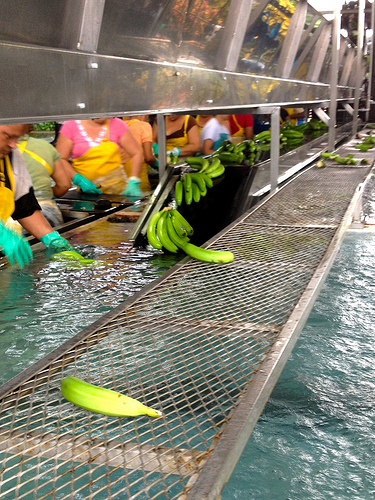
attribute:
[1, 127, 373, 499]
shelf — metal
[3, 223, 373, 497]
water — large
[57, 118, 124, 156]
shirt — white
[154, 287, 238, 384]
grate — large, silver, iron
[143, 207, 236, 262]
banana — green, yellow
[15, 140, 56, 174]
strap — yellow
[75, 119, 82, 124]
dot — white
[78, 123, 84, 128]
dot — white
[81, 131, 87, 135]
dot — white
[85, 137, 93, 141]
dot — white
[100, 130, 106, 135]
dot — white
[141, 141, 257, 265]
bananas — green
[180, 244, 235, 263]
banana — single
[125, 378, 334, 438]
object — black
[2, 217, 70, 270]
gloves — teal